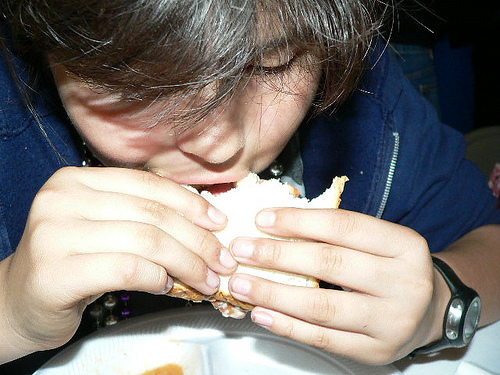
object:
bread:
[165, 167, 347, 320]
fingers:
[255, 207, 398, 259]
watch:
[409, 254, 483, 361]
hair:
[3, 2, 378, 132]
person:
[0, 4, 499, 375]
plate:
[33, 306, 398, 375]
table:
[2, 254, 494, 372]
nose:
[176, 114, 247, 164]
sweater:
[2, 32, 494, 322]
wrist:
[424, 242, 482, 354]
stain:
[137, 363, 183, 374]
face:
[464, 302, 480, 340]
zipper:
[365, 128, 401, 220]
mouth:
[199, 181, 236, 196]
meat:
[284, 183, 301, 198]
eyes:
[107, 56, 185, 83]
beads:
[90, 293, 131, 327]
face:
[50, 4, 321, 195]